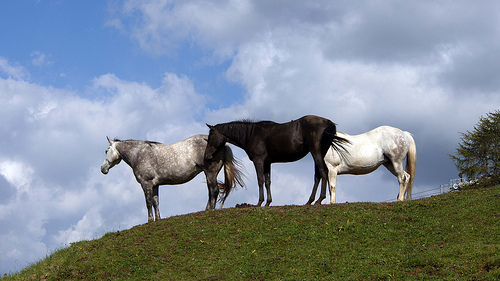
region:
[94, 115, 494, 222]
three horses standing on a hill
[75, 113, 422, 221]
three different colored horses facing the same direction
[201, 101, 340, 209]
black horse with a blue sky background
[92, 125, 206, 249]
gray and white speckled horse standing on a hill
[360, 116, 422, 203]
back end of a white horse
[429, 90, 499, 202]
bristly branched tree in the distance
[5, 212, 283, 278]
a green hill with a cloudy sky in the background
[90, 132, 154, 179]
a gray speckled horse head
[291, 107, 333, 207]
back end of a black horse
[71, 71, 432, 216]
black horse in the middle of lighter colored horses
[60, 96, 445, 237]
three horses on a hilltop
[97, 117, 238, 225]
this horse is a dappled grey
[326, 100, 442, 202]
this horse is an appaloosa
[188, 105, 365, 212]
this horse is a dark bay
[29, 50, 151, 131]
the sky has puffy white clouds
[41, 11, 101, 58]
this part of the sky is very blue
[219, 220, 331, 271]
the grass is a nice shade of green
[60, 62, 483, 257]
the horses are magnificent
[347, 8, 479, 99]
there may be a storm rolling in.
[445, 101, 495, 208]
a tree stands in the background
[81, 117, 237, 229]
horse is bulky and grey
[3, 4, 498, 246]
the cloudy sky above the horses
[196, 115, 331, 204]
the black horse in the middle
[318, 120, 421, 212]
the white horse in the back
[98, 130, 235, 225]
the grey horse in the front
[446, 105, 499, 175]
the bush on the hill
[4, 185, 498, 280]
the hill that the horses are standing on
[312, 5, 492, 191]
the dark clouds in the sky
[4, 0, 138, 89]
a patch of blue sky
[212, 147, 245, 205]
the tail of the grey horse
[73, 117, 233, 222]
horse is grey with white spots